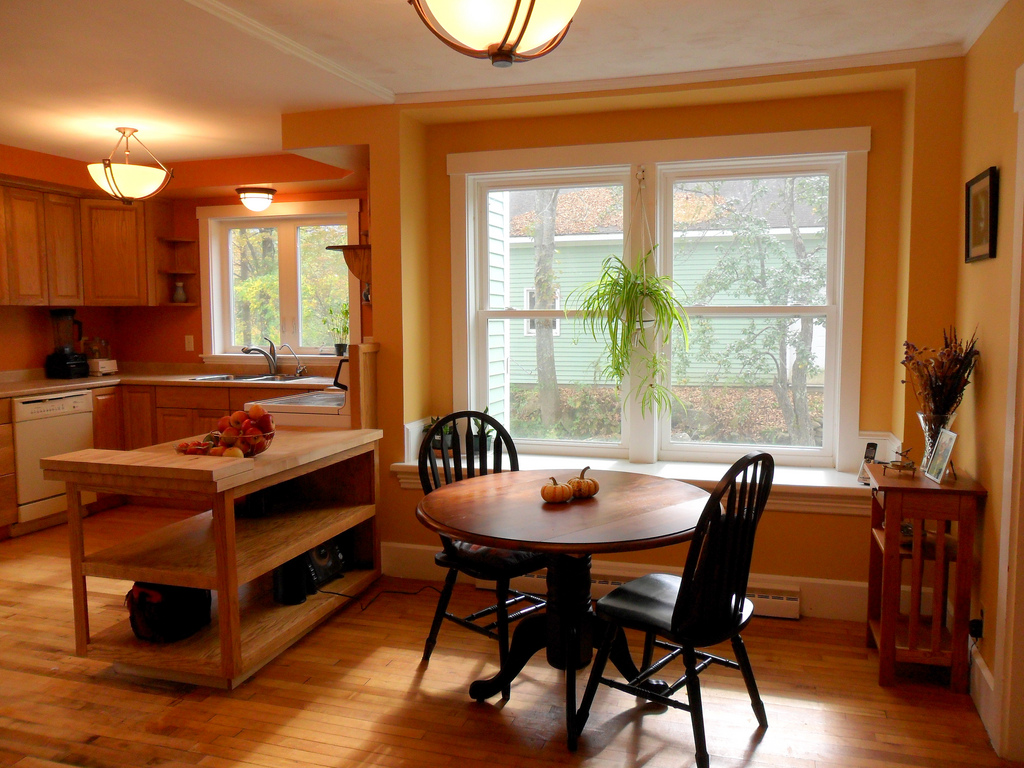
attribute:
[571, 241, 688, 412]
leaves — green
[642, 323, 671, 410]
leaves — green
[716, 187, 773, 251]
leaves — green